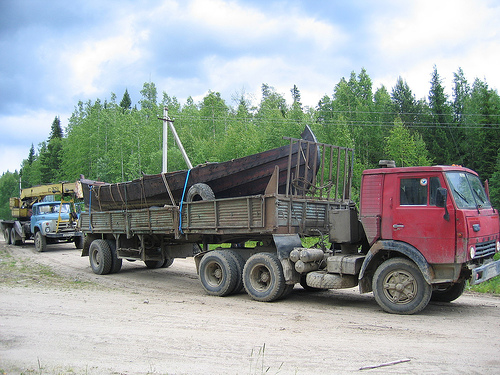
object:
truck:
[80, 123, 499, 315]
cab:
[330, 162, 499, 309]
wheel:
[366, 256, 436, 318]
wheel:
[240, 251, 283, 302]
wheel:
[195, 251, 240, 294]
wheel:
[87, 237, 111, 278]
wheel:
[429, 271, 470, 309]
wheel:
[143, 247, 166, 270]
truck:
[1, 188, 83, 254]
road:
[0, 226, 499, 374]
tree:
[46, 116, 61, 189]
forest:
[0, 81, 499, 207]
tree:
[22, 146, 36, 189]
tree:
[413, 71, 470, 173]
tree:
[454, 82, 499, 179]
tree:
[344, 69, 381, 183]